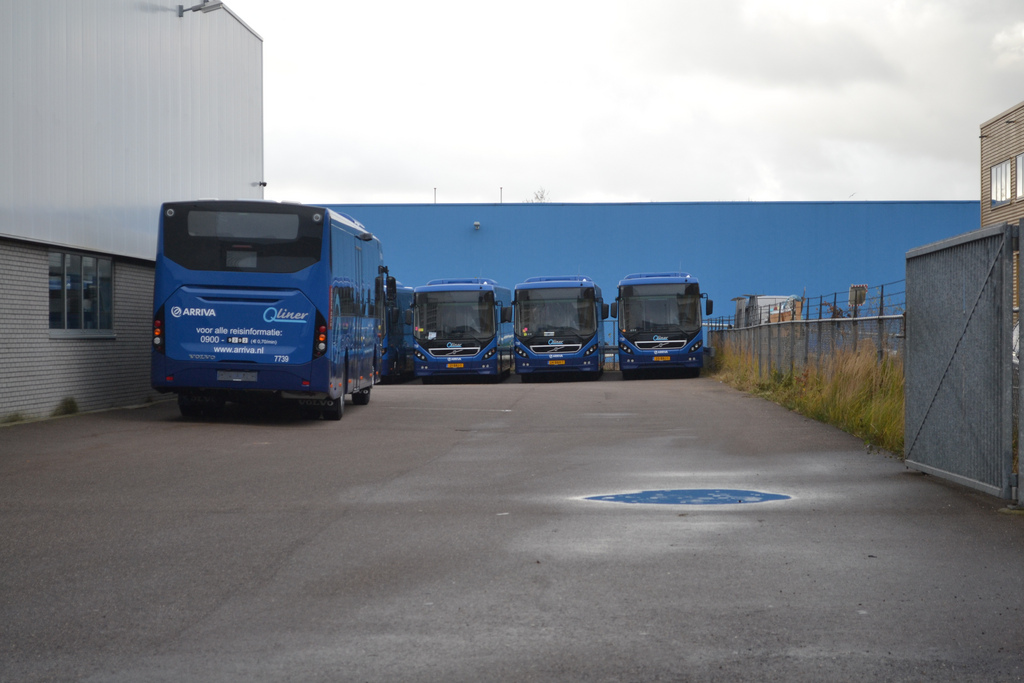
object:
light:
[187, 2, 223, 13]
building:
[0, 0, 265, 427]